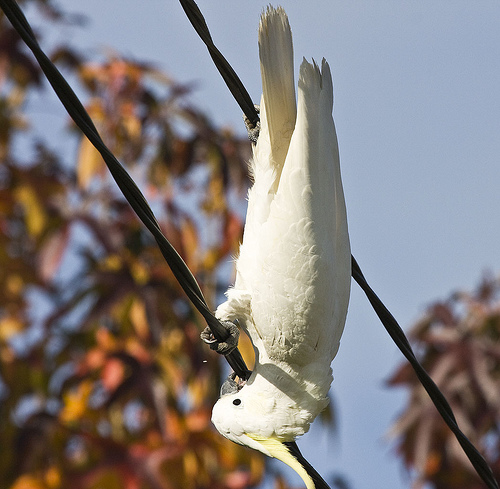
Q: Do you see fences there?
A: No, there are no fences.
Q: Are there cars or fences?
A: No, there are no fences or cars.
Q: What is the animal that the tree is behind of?
A: The animal is a bird.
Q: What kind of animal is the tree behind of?
A: The tree is behind the bird.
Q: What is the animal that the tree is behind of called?
A: The animal is a bird.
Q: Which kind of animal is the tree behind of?
A: The tree is behind the bird.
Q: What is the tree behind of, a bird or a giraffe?
A: The tree is behind a bird.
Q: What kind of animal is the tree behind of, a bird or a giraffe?
A: The tree is behind a bird.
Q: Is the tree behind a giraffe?
A: No, the tree is behind a bird.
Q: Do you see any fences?
A: No, there are no fences.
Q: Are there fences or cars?
A: No, there are no fences or cars.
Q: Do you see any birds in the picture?
A: Yes, there is a bird.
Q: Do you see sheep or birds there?
A: Yes, there is a bird.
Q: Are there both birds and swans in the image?
A: No, there is a bird but no swans.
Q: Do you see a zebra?
A: No, there are no zebras.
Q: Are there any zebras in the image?
A: No, there are no zebras.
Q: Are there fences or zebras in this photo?
A: No, there are no zebras or fences.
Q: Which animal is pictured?
A: The animal is a bird.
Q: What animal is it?
A: The animal is a bird.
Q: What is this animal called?
A: This is a bird.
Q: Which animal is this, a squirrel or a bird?
A: This is a bird.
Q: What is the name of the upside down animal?
A: The animal is a bird.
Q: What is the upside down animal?
A: The animal is a bird.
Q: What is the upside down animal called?
A: The animal is a bird.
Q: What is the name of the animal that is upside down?
A: The animal is a bird.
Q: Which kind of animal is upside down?
A: The animal is a bird.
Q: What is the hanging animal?
A: The animal is a bird.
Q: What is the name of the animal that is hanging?
A: The animal is a bird.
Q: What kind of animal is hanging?
A: The animal is a bird.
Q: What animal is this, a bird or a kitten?
A: This is a bird.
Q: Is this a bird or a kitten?
A: This is a bird.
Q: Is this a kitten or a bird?
A: This is a bird.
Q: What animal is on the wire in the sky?
A: The animal is a bird.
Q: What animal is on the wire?
A: The animal is a bird.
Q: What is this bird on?
A: The bird is on the wire.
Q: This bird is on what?
A: The bird is on the wire.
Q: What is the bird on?
A: The bird is on the wire.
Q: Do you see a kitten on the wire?
A: No, there is a bird on the wire.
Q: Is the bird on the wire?
A: Yes, the bird is on the wire.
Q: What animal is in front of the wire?
A: The animal is a bird.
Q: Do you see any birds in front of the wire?
A: Yes, there is a bird in front of the wire.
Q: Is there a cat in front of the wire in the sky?
A: No, there is a bird in front of the wire.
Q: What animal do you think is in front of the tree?
A: The bird is in front of the tree.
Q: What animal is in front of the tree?
A: The animal is a bird.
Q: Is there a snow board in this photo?
A: No, there are no snowboards.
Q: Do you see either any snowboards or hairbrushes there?
A: No, there are no snowboards or hairbrushes.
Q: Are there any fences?
A: No, there are no fences.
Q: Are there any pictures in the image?
A: No, there are no pictures.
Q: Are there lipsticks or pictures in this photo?
A: No, there are no pictures or lipsticks.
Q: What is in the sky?
A: The wire is in the sky.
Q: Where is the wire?
A: The wire is in the sky.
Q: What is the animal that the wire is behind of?
A: The animal is a bird.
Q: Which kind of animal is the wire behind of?
A: The wire is behind the bird.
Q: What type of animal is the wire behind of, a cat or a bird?
A: The wire is behind a bird.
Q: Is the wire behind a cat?
A: No, the wire is behind a bird.